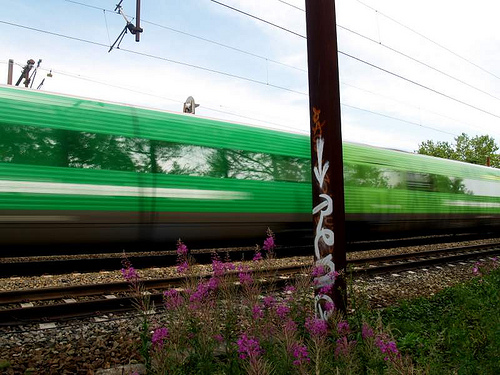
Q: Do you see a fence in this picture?
A: No, there are no fences.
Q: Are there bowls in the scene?
A: No, there are no bowls.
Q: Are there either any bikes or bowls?
A: No, there are no bowls or bikes.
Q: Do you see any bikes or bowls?
A: No, there are no bowls or bikes.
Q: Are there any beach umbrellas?
A: No, there are no beach umbrellas.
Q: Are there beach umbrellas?
A: No, there are no beach umbrellas.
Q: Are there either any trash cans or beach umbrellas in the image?
A: No, there are no beach umbrellas or trash cans.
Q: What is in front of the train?
A: The pole is in front of the train.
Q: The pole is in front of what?
A: The pole is in front of the train.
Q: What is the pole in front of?
A: The pole is in front of the train.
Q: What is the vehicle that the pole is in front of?
A: The vehicle is a train.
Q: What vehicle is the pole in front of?
A: The pole is in front of the train.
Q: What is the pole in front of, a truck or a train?
A: The pole is in front of a train.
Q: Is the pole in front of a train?
A: Yes, the pole is in front of a train.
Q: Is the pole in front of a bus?
A: No, the pole is in front of a train.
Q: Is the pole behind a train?
A: No, the pole is in front of a train.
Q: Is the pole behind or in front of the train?
A: The pole is in front of the train.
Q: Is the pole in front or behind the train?
A: The pole is in front of the train.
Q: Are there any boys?
A: No, there are no boys.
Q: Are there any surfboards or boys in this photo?
A: No, there are no boys or surfboards.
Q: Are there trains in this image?
A: Yes, there is a train.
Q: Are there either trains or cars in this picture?
A: Yes, there is a train.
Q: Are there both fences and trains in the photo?
A: No, there is a train but no fences.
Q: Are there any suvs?
A: No, there are no suvs.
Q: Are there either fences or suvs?
A: No, there are no suvs or fences.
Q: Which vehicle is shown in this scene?
A: The vehicle is a train.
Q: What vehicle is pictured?
A: The vehicle is a train.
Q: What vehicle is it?
A: The vehicle is a train.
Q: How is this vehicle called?
A: That is a train.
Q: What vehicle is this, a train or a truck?
A: That is a train.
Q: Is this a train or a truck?
A: This is a train.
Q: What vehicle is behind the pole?
A: The vehicle is a train.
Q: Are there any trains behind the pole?
A: Yes, there is a train behind the pole.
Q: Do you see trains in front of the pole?
A: No, the train is behind the pole.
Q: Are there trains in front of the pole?
A: No, the train is behind the pole.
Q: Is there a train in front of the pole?
A: No, the train is behind the pole.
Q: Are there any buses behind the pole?
A: No, there is a train behind the pole.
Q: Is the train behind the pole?
A: Yes, the train is behind the pole.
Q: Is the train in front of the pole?
A: No, the train is behind the pole.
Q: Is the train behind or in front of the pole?
A: The train is behind the pole.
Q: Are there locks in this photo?
A: No, there are no locks.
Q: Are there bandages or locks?
A: No, there are no locks or bandages.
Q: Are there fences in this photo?
A: No, there are no fences.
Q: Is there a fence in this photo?
A: No, there are no fences.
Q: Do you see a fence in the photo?
A: No, there are no fences.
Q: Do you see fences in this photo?
A: No, there are no fences.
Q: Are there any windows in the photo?
A: Yes, there is a window.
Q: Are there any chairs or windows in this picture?
A: Yes, there is a window.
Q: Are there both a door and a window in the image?
A: No, there is a window but no doors.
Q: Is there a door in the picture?
A: No, there are no doors.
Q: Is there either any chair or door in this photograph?
A: No, there are no doors or chairs.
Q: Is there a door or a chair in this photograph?
A: No, there are no doors or chairs.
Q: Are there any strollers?
A: No, there are no strollers.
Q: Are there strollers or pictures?
A: No, there are no strollers or pictures.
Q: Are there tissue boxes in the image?
A: No, there are no tissue boxes.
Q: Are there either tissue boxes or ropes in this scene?
A: No, there are no tissue boxes or ropes.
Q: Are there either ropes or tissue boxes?
A: No, there are no tissue boxes or ropes.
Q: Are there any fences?
A: No, there are no fences.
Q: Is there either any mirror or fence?
A: No, there are no fences or mirrors.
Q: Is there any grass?
A: Yes, there is grass.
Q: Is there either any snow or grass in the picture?
A: Yes, there is grass.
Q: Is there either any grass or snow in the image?
A: Yes, there is grass.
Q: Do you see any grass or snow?
A: Yes, there is grass.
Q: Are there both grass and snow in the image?
A: No, there is grass but no snow.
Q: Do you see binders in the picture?
A: No, there are no binders.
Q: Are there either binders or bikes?
A: No, there are no binders or bikes.